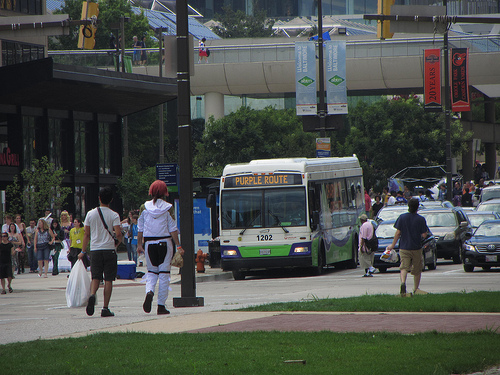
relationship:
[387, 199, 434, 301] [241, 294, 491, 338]
man on sidewalk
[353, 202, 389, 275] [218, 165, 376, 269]
person boarding bus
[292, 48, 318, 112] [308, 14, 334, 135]
banner on pole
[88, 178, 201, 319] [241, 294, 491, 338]
couple on sidewalk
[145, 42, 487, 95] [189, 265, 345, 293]
bridge over street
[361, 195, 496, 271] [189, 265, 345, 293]
cars on street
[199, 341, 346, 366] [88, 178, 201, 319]
grass near couple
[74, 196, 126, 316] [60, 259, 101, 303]
man carries bag